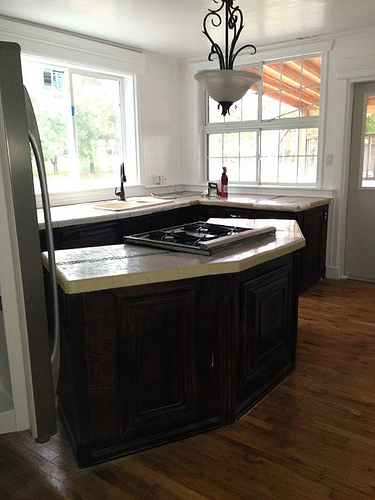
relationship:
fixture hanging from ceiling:
[193, 0, 262, 117] [3, 4, 362, 55]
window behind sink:
[20, 50, 141, 210] [98, 188, 175, 212]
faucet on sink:
[115, 162, 127, 201] [94, 189, 179, 214]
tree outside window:
[32, 79, 115, 175] [17, 53, 143, 185]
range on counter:
[146, 218, 244, 243] [46, 214, 297, 304]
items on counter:
[199, 161, 229, 196] [163, 187, 333, 209]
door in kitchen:
[331, 75, 363, 282] [0, 0, 374, 497]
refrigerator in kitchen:
[0, 39, 61, 443] [0, 0, 374, 497]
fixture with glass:
[198, 1, 255, 120] [191, 66, 263, 106]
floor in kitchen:
[0, 277, 373, 498] [0, 0, 374, 497]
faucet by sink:
[113, 161, 127, 201] [89, 195, 170, 211]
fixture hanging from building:
[193, 0, 262, 117] [0, 0, 373, 498]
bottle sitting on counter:
[220, 165, 228, 197] [34, 191, 331, 229]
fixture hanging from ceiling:
[193, 0, 262, 117] [2, 1, 363, 60]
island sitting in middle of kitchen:
[38, 214, 307, 470] [0, 0, 374, 497]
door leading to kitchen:
[338, 75, 375, 283] [0, 0, 374, 497]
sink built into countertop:
[88, 196, 173, 212] [37, 189, 330, 230]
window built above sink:
[21, 60, 130, 195] [89, 194, 174, 213]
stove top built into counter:
[120, 218, 276, 256] [41, 215, 308, 295]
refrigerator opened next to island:
[0, 39, 61, 443] [38, 214, 307, 470]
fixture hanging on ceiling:
[193, 0, 262, 117] [103, 2, 339, 124]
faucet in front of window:
[115, 162, 127, 201] [31, 53, 194, 221]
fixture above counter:
[193, 0, 262, 117] [42, 199, 308, 343]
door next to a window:
[338, 75, 375, 283] [205, 45, 341, 219]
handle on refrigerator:
[21, 120, 66, 370] [0, 36, 94, 434]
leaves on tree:
[80, 116, 92, 135] [66, 69, 131, 202]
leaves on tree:
[50, 113, 62, 127] [25, 90, 100, 202]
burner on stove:
[160, 214, 247, 265] [139, 212, 268, 276]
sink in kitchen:
[93, 199, 174, 212] [0, 0, 374, 497]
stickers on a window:
[37, 67, 71, 91] [19, 56, 139, 193]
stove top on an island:
[123, 221, 277, 256] [38, 214, 307, 470]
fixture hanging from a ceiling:
[193, 0, 262, 117] [3, 4, 362, 55]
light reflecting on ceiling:
[248, 6, 323, 38] [5, 7, 362, 58]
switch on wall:
[323, 152, 333, 169] [180, 29, 363, 279]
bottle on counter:
[220, 167, 228, 197] [29, 189, 329, 233]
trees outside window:
[32, 99, 128, 175] [21, 67, 132, 179]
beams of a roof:
[245, 57, 332, 114] [244, 60, 321, 108]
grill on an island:
[121, 215, 277, 257] [38, 214, 307, 470]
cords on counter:
[150, 177, 184, 201] [34, 191, 331, 229]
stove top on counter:
[123, 221, 277, 256] [1, 2, 365, 487]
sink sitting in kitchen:
[93, 199, 174, 212] [0, 0, 374, 497]